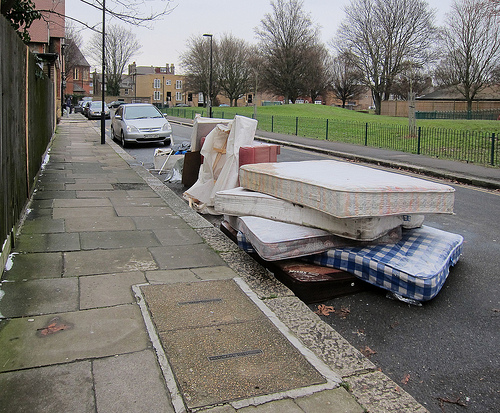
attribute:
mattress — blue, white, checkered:
[234, 222, 465, 303]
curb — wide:
[89, 121, 430, 411]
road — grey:
[91, 108, 498, 408]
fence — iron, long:
[156, 101, 497, 169]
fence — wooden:
[379, 98, 499, 118]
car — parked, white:
[110, 102, 172, 146]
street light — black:
[202, 32, 214, 115]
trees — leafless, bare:
[183, 0, 498, 120]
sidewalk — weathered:
[0, 108, 428, 412]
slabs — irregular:
[3, 104, 376, 413]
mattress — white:
[236, 157, 457, 219]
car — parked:
[86, 101, 111, 119]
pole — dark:
[100, 1, 107, 144]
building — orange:
[130, 70, 198, 107]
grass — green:
[158, 99, 497, 166]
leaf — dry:
[315, 302, 334, 318]